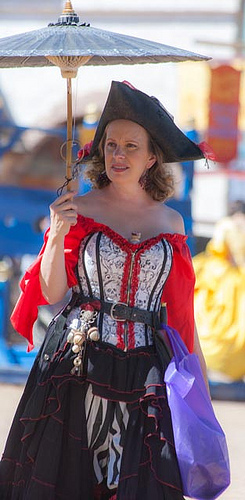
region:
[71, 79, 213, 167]
Pirate hat.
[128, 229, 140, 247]
Bottle peeking out of a woman's top.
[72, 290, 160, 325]
Belt being worn by woman.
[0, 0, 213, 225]
A parisol for shading from sun.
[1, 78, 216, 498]
Woman dressed as a pirate.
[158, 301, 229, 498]
Purple bag handing from handle of sword.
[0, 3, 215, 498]
Woman holding a parisol.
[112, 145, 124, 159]
A woman's nose.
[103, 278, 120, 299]
Skull on bodice of dress.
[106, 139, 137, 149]
Woman's eyes.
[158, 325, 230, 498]
purple bag attached to belt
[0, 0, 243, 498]
woman in costume holding an umbrella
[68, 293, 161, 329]
black belt with silver buckle around waist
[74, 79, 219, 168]
blac pirate hat with red flowers on head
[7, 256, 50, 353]
red frilly sleeve hanging from arm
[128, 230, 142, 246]
bottle cap sticking out of bodice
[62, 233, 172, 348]
black and white bodice with red lace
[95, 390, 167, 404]
red piping on black skirt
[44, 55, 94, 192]
bamboo handle on umbrella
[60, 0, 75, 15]
bamboo top on umbrella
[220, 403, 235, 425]
this is the ground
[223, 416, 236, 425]
the ground is clean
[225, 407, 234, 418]
the ground is grey in color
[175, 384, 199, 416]
this is a paper bag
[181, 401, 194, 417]
the bag is purple in color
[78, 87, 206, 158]
this is a hat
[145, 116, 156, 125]
the hair is black in color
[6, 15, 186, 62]
this is an umbrella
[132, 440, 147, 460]
the dress is black in color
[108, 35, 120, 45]
the umbrella is open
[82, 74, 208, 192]
girl in a boaters hat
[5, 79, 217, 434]
girl dressed in a scary uniform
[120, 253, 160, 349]
skulls and bones on the cloths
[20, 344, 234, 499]
random pattern skirt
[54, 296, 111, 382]
bones and skulls on a chain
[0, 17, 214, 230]
old time umbrella all wood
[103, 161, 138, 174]
girls mouth with lipstick on it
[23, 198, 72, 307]
sun hitting a forearm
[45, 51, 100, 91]
wooden umbrella opener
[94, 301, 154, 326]
black belt being secured by metal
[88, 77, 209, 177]
black triangular hat on the head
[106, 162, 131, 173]
lips are parted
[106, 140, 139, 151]
a pair of eyes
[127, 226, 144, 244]
bottle sticking out of the top of the shirt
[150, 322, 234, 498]
purple bag attached to the hip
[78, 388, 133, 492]
black and white stripes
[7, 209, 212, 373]
corset on the torso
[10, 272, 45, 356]
fabric hanging down from the sleeve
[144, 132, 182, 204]
hair sticking out of the hat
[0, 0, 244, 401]
background is blurry